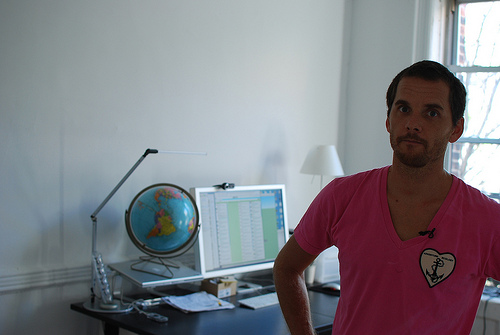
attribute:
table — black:
[68, 268, 340, 333]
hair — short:
[373, 59, 466, 118]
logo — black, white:
[413, 244, 465, 288]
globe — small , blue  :
[104, 160, 202, 268]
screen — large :
[175, 182, 305, 297]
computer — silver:
[146, 155, 310, 305]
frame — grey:
[184, 176, 303, 280]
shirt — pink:
[294, 166, 499, 332]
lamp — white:
[298, 141, 348, 193]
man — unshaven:
[306, 41, 487, 301]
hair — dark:
[384, 59, 466, 121]